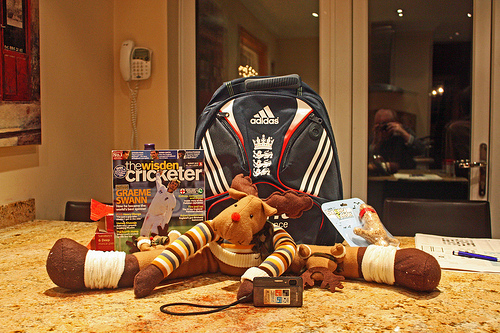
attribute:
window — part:
[221, 38, 261, 64]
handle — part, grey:
[247, 69, 298, 88]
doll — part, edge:
[239, 238, 319, 284]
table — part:
[28, 292, 74, 311]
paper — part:
[435, 249, 456, 261]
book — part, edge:
[120, 188, 209, 231]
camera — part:
[202, 149, 232, 173]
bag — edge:
[176, 123, 267, 152]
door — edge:
[322, 0, 386, 96]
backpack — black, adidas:
[199, 111, 301, 168]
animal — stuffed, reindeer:
[225, 207, 261, 225]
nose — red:
[228, 219, 242, 229]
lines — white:
[303, 151, 325, 162]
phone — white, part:
[119, 39, 156, 92]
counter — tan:
[60, 310, 84, 319]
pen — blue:
[459, 241, 478, 262]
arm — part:
[411, 133, 422, 166]